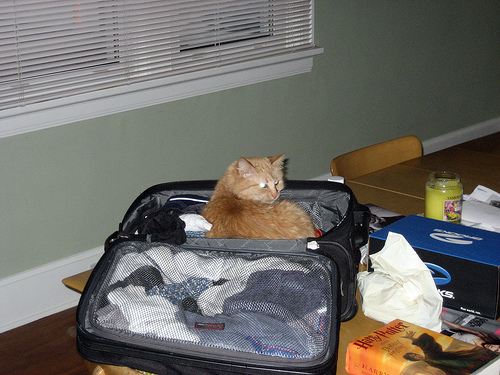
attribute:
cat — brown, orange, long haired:
[205, 155, 323, 242]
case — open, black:
[73, 179, 366, 375]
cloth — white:
[357, 232, 447, 331]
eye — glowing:
[261, 182, 268, 189]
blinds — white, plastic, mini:
[2, 1, 321, 121]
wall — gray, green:
[1, 1, 499, 282]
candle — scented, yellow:
[424, 168, 465, 224]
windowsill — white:
[1, 41, 331, 138]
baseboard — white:
[1, 112, 500, 341]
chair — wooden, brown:
[327, 133, 427, 182]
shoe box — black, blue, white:
[362, 210, 499, 321]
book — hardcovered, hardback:
[344, 319, 500, 375]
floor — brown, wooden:
[1, 300, 92, 375]